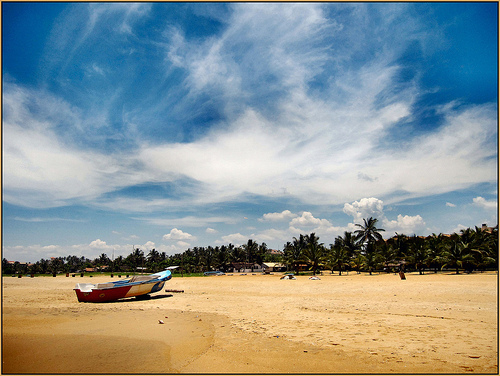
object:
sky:
[2, 2, 498, 263]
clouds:
[1, 1, 499, 208]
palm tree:
[334, 229, 362, 275]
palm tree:
[299, 229, 326, 278]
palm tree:
[241, 236, 260, 274]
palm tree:
[129, 245, 146, 279]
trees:
[350, 215, 387, 275]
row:
[0, 215, 498, 281]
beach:
[1, 270, 497, 375]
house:
[260, 259, 291, 272]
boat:
[71, 266, 174, 304]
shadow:
[111, 290, 175, 303]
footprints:
[453, 348, 486, 361]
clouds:
[284, 209, 332, 225]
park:
[1, 215, 499, 280]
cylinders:
[50, 270, 62, 276]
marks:
[0, 304, 499, 375]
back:
[72, 273, 132, 306]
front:
[151, 268, 176, 291]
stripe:
[125, 280, 155, 300]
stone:
[133, 292, 150, 301]